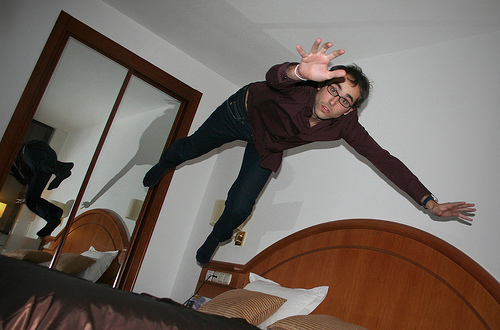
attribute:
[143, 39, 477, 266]
man — mid air, jumping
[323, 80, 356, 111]
glasses — black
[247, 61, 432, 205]
shirt — long sleeved, maroon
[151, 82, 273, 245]
jeans — blue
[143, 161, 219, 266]
socks — black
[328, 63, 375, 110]
hair — brown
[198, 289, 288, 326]
pillow — striped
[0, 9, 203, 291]
mirror — large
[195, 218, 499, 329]
headboard — wooden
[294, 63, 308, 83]
bracelet — white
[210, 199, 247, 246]
lamp — mounted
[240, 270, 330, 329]
pillow — white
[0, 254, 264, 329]
comforter — brown